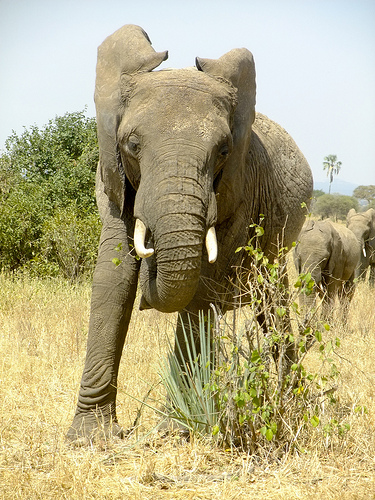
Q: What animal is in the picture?
A: Elephant.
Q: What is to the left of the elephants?
A: Bushes.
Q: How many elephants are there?
A: 3.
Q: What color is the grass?
A: Brown.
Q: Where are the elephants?
A: In the desert.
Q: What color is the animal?
A: Gray.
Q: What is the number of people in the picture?
A: None.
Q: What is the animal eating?
A: Plants.